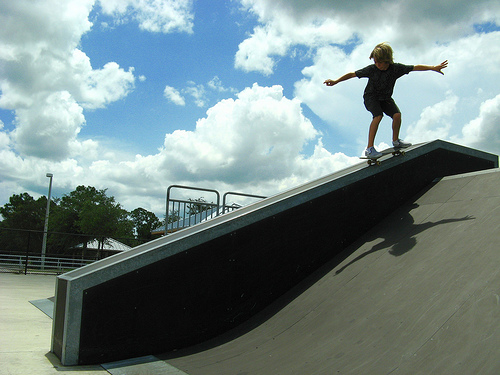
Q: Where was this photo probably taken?
A: Skate park.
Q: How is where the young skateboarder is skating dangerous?
A: He could fall over side.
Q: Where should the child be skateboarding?
A: On the actual ramp.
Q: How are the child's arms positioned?
A: Out to side.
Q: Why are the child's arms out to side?
A: For balance.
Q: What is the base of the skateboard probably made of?
A: Wood.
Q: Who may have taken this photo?
A: Friend of skateboarder.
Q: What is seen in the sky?
A: Clouds.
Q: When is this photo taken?
A: In the day.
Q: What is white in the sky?
A: Clouds.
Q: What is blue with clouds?
A: The sky.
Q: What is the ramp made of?
A: Concrete.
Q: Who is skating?
A: The boy.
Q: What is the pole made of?
A: Metal.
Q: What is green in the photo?
A: Trees.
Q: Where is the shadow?
A: On the ramp.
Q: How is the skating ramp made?
A: Of concrete.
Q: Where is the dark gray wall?
A: On the ramp.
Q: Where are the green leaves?
A: On the trees.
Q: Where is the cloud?
A: In the sky.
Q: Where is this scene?
A: Skate park.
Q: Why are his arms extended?
A: Leverage.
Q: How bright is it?
A: Moderately.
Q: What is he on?
A: Skateboard.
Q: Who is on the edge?
A: Skateboarder.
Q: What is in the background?
A: Trees.